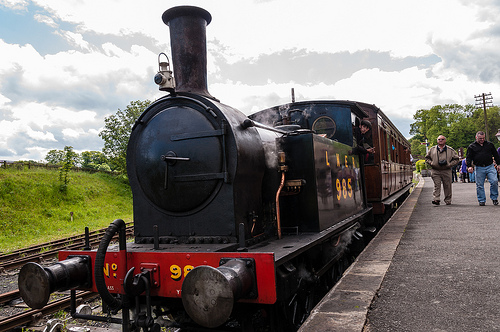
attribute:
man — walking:
[424, 135, 460, 205]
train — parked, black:
[18, 5, 415, 332]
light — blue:
[392, 145, 395, 150]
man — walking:
[467, 131, 499, 207]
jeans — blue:
[476, 165, 499, 203]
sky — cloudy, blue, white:
[1, 0, 499, 168]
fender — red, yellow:
[59, 249, 277, 304]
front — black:
[127, 94, 237, 242]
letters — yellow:
[326, 151, 357, 169]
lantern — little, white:
[154, 52, 175, 90]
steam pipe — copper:
[275, 151, 285, 237]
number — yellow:
[169, 265, 194, 279]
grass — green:
[0, 164, 133, 258]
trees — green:
[410, 103, 498, 158]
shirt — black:
[467, 141, 499, 167]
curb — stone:
[295, 174, 425, 331]